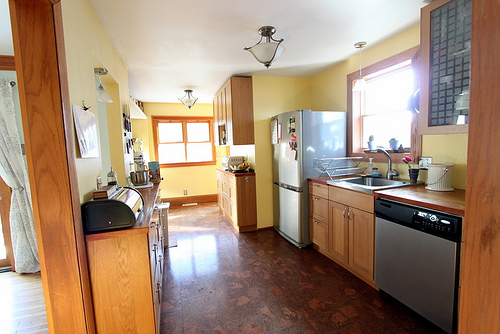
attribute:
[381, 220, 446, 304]
dishwasher — gray, silver, black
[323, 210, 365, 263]
cabinet — wood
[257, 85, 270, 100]
wall — wood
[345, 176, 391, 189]
sink — metal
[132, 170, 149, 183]
bowl — silver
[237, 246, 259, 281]
floor — brown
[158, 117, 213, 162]
window — open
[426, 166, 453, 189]
pot — white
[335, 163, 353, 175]
rack — white